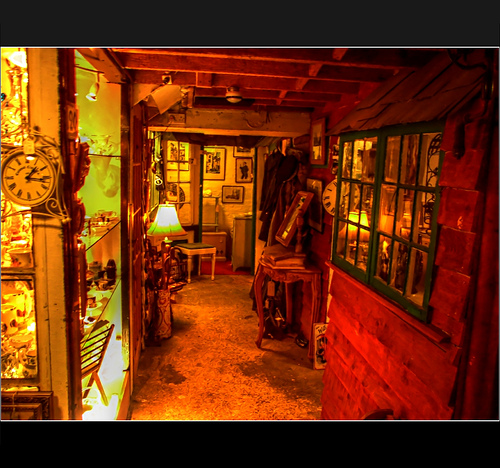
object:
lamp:
[146, 204, 189, 240]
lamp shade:
[147, 203, 185, 240]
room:
[2, 45, 500, 417]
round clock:
[321, 176, 361, 217]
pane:
[355, 225, 372, 273]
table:
[253, 247, 322, 359]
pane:
[340, 140, 351, 181]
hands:
[28, 166, 38, 178]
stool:
[174, 242, 216, 282]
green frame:
[374, 122, 445, 322]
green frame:
[331, 129, 382, 287]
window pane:
[351, 225, 373, 275]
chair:
[173, 243, 216, 284]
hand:
[27, 177, 44, 180]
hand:
[25, 166, 39, 180]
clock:
[0, 149, 57, 208]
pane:
[405, 245, 428, 307]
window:
[330, 118, 448, 324]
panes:
[376, 183, 399, 236]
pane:
[343, 222, 359, 267]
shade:
[140, 204, 187, 236]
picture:
[204, 146, 227, 181]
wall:
[149, 132, 255, 271]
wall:
[315, 326, 434, 422]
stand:
[251, 168, 320, 358]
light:
[146, 202, 188, 288]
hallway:
[175, 269, 259, 420]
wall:
[283, 135, 334, 255]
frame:
[31, 49, 64, 419]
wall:
[300, 135, 331, 342]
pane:
[347, 178, 363, 223]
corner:
[145, 129, 176, 290]